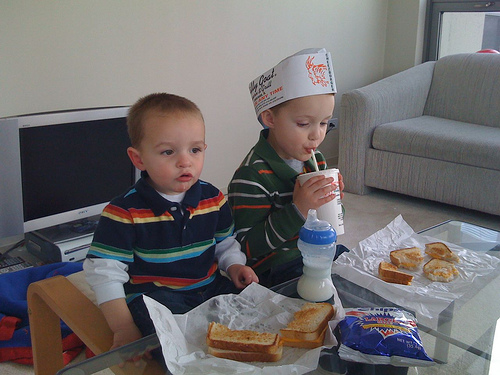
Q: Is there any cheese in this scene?
A: Yes, there is cheese.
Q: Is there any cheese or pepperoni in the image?
A: Yes, there is cheese.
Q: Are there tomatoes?
A: No, there are no tomatoes.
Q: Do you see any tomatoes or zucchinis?
A: No, there are no tomatoes or zucchinis.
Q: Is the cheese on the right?
A: Yes, the cheese is on the right of the image.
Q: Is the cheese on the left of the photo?
A: No, the cheese is on the right of the image.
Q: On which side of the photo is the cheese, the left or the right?
A: The cheese is on the right of the image.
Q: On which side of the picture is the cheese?
A: The cheese is on the right of the image.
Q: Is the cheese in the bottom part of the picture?
A: Yes, the cheese is in the bottom of the image.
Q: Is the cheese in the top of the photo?
A: No, the cheese is in the bottom of the image.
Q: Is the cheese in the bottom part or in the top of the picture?
A: The cheese is in the bottom of the image.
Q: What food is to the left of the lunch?
A: The food is cheese.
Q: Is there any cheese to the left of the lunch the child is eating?
A: Yes, there is cheese to the left of the lunch.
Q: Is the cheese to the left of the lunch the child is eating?
A: Yes, the cheese is to the left of the lunch.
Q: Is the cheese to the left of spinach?
A: No, the cheese is to the left of the lunch.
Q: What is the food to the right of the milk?
A: The food is cheese.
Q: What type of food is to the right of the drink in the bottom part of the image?
A: The food is cheese.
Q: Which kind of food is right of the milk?
A: The food is cheese.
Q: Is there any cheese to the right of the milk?
A: Yes, there is cheese to the right of the milk.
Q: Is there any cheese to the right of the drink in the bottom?
A: Yes, there is cheese to the right of the milk.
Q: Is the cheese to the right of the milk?
A: Yes, the cheese is to the right of the milk.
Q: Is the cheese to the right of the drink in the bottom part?
A: Yes, the cheese is to the right of the milk.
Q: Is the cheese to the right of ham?
A: No, the cheese is to the right of the milk.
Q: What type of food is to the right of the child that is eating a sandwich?
A: The food is cheese.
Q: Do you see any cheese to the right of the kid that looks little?
A: Yes, there is cheese to the right of the kid.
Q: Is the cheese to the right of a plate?
A: No, the cheese is to the right of a child.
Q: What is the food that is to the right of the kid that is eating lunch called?
A: The food is cheese.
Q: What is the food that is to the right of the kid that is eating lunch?
A: The food is cheese.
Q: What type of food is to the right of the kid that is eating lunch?
A: The food is cheese.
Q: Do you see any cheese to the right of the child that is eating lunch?
A: Yes, there is cheese to the right of the child.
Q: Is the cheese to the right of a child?
A: Yes, the cheese is to the right of a child.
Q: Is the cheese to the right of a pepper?
A: No, the cheese is to the right of a child.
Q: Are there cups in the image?
A: Yes, there is a cup.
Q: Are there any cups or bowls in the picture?
A: Yes, there is a cup.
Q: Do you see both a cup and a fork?
A: No, there is a cup but no forks.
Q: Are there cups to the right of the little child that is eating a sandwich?
A: Yes, there is a cup to the right of the child.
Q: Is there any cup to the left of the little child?
A: No, the cup is to the right of the kid.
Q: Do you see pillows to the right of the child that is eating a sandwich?
A: No, there is a cup to the right of the child.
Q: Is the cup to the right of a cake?
A: No, the cup is to the right of a child.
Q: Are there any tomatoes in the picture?
A: No, there are no tomatoes.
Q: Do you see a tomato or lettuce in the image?
A: No, there are no tomatoes or lettuce.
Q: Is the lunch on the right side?
A: Yes, the lunch is on the right of the image.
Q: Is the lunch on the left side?
A: No, the lunch is on the right of the image.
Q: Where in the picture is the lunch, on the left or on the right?
A: The lunch is on the right of the image.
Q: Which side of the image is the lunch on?
A: The lunch is on the right of the image.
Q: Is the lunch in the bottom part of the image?
A: Yes, the lunch is in the bottom of the image.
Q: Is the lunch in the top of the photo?
A: No, the lunch is in the bottom of the image.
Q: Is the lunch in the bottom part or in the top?
A: The lunch is in the bottom of the image.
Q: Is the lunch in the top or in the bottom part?
A: The lunch is in the bottom of the image.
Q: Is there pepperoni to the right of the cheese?
A: No, there is lunch to the right of the cheese.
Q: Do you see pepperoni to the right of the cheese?
A: No, there is lunch to the right of the cheese.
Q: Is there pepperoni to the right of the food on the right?
A: No, there is lunch to the right of the cheese.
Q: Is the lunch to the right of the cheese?
A: Yes, the lunch is to the right of the cheese.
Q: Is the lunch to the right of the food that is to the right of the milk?
A: Yes, the lunch is to the right of the cheese.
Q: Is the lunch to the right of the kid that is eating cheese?
A: Yes, the lunch is to the right of the child.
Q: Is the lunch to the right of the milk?
A: Yes, the lunch is to the right of the milk.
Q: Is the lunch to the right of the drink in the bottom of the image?
A: Yes, the lunch is to the right of the milk.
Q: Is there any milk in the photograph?
A: Yes, there is milk.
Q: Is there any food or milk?
A: Yes, there is milk.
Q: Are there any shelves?
A: No, there are no shelves.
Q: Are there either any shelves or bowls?
A: No, there are no shelves or bowls.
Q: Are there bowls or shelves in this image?
A: No, there are no shelves or bowls.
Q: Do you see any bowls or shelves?
A: No, there are no shelves or bowls.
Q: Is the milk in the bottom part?
A: Yes, the milk is in the bottom of the image.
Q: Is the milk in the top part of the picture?
A: No, the milk is in the bottom of the image.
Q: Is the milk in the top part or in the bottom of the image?
A: The milk is in the bottom of the image.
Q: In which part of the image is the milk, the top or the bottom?
A: The milk is in the bottom of the image.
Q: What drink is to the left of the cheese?
A: The drink is milk.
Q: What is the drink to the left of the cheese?
A: The drink is milk.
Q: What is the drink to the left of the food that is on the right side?
A: The drink is milk.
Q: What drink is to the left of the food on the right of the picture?
A: The drink is milk.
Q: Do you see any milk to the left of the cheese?
A: Yes, there is milk to the left of the cheese.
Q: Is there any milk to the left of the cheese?
A: Yes, there is milk to the left of the cheese.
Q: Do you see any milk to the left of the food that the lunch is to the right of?
A: Yes, there is milk to the left of the cheese.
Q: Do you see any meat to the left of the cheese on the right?
A: No, there is milk to the left of the cheese.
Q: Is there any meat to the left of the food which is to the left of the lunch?
A: No, there is milk to the left of the cheese.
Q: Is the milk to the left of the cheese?
A: Yes, the milk is to the left of the cheese.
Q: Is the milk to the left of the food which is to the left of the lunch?
A: Yes, the milk is to the left of the cheese.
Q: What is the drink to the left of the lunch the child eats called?
A: The drink is milk.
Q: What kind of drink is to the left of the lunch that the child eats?
A: The drink is milk.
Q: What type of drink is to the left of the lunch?
A: The drink is milk.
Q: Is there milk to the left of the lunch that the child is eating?
A: Yes, there is milk to the left of the lunch.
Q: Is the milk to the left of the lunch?
A: Yes, the milk is to the left of the lunch.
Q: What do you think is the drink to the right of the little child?
A: The drink is milk.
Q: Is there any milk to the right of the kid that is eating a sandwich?
A: Yes, there is milk to the right of the child.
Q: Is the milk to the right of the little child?
A: Yes, the milk is to the right of the kid.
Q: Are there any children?
A: Yes, there is a child.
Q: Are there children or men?
A: Yes, there is a child.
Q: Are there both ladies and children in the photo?
A: No, there is a child but no ladies.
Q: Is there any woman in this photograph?
A: No, there are no women.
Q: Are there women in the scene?
A: No, there are no women.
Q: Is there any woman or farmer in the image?
A: No, there are no women or farmers.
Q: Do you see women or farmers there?
A: No, there are no women or farmers.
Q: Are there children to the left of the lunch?
A: Yes, there is a child to the left of the lunch.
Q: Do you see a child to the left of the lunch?
A: Yes, there is a child to the left of the lunch.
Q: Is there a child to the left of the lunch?
A: Yes, there is a child to the left of the lunch.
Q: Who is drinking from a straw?
A: The kid is drinking from a straw.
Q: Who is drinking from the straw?
A: The kid is drinking from a straw.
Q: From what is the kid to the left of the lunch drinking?
A: The kid is drinking from a straw.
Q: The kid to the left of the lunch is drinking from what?
A: The kid is drinking from a straw.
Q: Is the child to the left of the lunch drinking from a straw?
A: Yes, the child is drinking from a straw.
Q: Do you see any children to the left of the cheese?
A: Yes, there is a child to the left of the cheese.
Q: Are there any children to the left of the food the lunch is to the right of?
A: Yes, there is a child to the left of the cheese.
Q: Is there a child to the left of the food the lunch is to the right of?
A: Yes, there is a child to the left of the cheese.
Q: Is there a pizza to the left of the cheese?
A: No, there is a child to the left of the cheese.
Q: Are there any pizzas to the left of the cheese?
A: No, there is a child to the left of the cheese.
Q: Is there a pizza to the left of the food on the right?
A: No, there is a child to the left of the cheese.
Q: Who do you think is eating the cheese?
A: The kid is eating the cheese.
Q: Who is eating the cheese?
A: The kid is eating the cheese.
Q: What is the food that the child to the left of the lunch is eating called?
A: The food is cheese.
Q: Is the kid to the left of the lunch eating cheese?
A: Yes, the kid is eating cheese.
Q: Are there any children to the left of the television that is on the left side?
A: No, the child is to the right of the television.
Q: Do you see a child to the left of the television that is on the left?
A: No, the child is to the right of the television.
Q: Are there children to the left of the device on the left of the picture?
A: No, the child is to the right of the television.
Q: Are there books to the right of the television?
A: No, there is a child to the right of the television.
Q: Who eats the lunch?
A: The kid eats the lunch.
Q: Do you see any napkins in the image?
A: No, there are no napkins.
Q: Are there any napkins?
A: No, there are no napkins.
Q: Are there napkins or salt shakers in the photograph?
A: No, there are no napkins or salt shakers.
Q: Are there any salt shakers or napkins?
A: No, there are no napkins or salt shakers.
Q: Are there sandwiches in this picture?
A: Yes, there is a sandwich.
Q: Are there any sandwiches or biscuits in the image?
A: Yes, there is a sandwich.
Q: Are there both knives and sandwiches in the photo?
A: No, there is a sandwich but no knives.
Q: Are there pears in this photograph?
A: No, there are no pears.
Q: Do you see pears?
A: No, there are no pears.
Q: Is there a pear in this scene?
A: No, there are no pears.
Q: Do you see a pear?
A: No, there are no pears.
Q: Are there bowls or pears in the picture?
A: No, there are no pears or bowls.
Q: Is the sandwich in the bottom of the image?
A: Yes, the sandwich is in the bottom of the image.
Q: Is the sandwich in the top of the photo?
A: No, the sandwich is in the bottom of the image.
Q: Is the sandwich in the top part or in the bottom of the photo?
A: The sandwich is in the bottom of the image.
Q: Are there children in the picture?
A: Yes, there is a child.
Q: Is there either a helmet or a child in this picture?
A: Yes, there is a child.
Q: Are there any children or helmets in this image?
A: Yes, there is a child.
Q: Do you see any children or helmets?
A: Yes, there is a child.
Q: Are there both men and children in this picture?
A: No, there is a child but no men.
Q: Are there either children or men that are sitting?
A: Yes, the child is sitting.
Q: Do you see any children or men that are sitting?
A: Yes, the child is sitting.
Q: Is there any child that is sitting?
A: Yes, there is a child that is sitting.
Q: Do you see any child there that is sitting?
A: Yes, there is a child that is sitting.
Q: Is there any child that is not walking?
A: Yes, there is a child that is sitting.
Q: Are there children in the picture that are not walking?
A: Yes, there is a child that is sitting.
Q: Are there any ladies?
A: No, there are no ladies.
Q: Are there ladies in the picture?
A: No, there are no ladies.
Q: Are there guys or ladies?
A: No, there are no ladies or guys.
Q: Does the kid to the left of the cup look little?
A: Yes, the kid is little.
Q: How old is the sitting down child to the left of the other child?
A: The child is little.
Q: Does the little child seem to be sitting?
A: Yes, the kid is sitting.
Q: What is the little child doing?
A: The child is sitting.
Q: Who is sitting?
A: The kid is sitting.